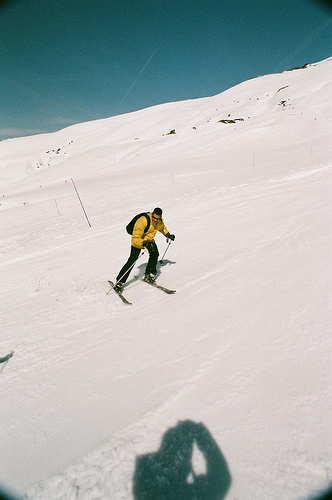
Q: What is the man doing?
A: Skiing.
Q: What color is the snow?
A: White.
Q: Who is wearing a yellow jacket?
A: The skier.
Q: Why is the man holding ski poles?
A: To ski.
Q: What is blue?
A: Sky.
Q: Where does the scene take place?
A: On a ski slope.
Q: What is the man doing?
A: Skiing.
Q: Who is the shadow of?
A: The cameraman.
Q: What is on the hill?
A: Snow.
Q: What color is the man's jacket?
A: Yellow.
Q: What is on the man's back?
A: Black backpack.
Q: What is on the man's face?
A: Sunglasses.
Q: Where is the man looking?
A: At the camera.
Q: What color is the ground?
A: White.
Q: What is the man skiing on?
A: A hill.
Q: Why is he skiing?
A: For fun.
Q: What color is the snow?
A: White.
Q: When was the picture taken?
A: Last winter.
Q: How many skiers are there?
A: One.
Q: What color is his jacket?
A: Yellow.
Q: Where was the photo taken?
A: The mountain.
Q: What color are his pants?
A: Black.